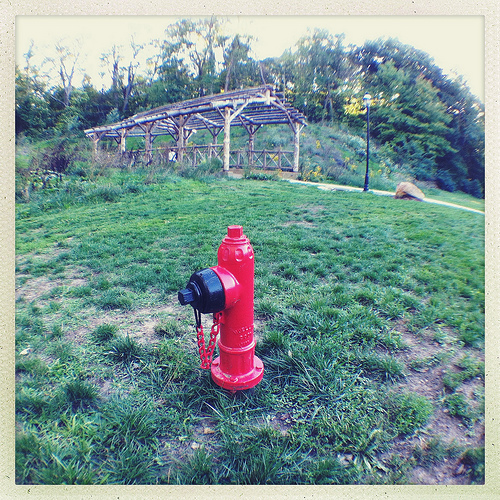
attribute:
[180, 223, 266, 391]
hydrant — red, black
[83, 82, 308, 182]
bridge — wooden, wood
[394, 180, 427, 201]
rock — large, brownish-grey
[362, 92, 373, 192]
lamp post — black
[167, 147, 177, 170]
person — walking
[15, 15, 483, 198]
trees — tall, green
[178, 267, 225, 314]
cap — black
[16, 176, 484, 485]
field — green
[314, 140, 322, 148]
flower — yellow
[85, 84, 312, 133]
roof — wooden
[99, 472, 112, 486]
grass — green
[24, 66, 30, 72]
leaf — green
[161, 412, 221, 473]
dirt — brown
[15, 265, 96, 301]
ground — brown